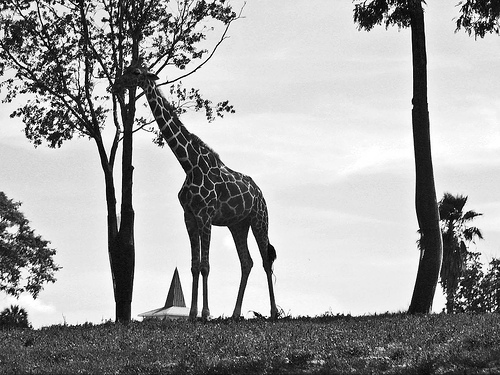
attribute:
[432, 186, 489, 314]
tree — distant, palm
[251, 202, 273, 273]
tail — black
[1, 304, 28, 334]
palm bush — small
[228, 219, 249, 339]
leg — powerful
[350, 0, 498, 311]
tree — leafy, green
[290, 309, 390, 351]
grass — short, mowed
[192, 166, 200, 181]
spot — brown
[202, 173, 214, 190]
spot — brown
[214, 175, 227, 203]
spot — brown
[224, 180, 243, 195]
spot — brown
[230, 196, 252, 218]
spot — brown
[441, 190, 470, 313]
palm tree — small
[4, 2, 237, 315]
tree — green, leafy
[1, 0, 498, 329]
sky — overcast, grey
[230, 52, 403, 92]
cloud — streak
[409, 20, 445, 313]
tree trunk — tall, dark